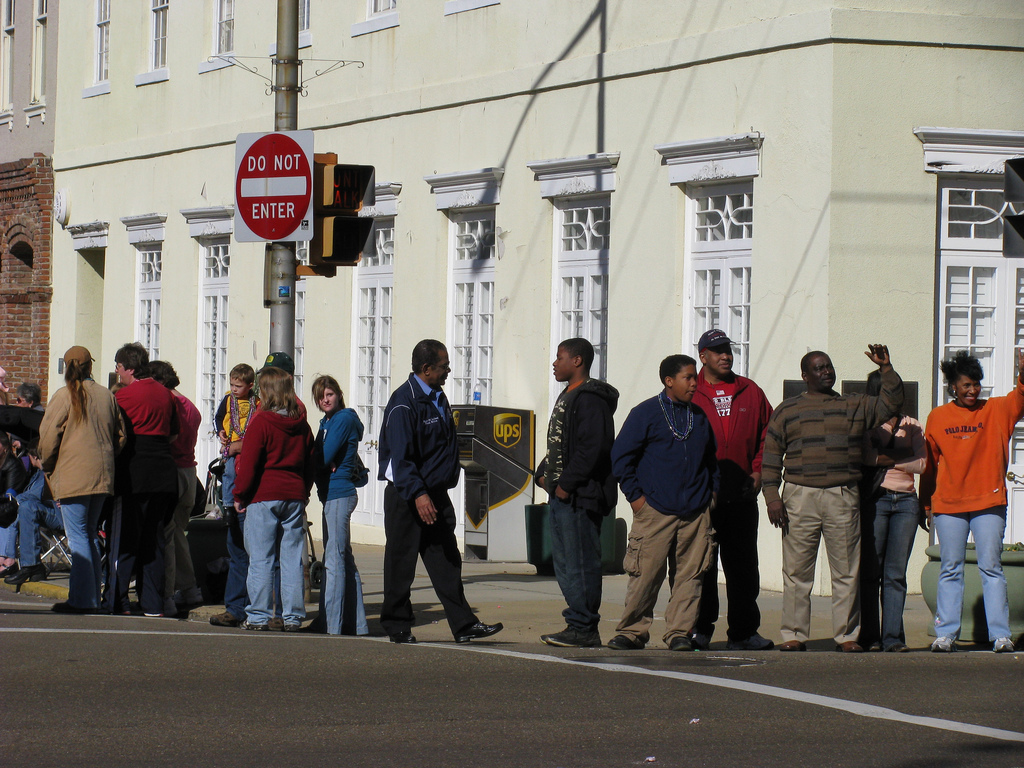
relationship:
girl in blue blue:
[308, 375, 372, 639] [611, 389, 721, 515]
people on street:
[14, 338, 1010, 655] [3, 575, 1023, 761]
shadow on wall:
[470, 6, 608, 390] [1, 2, 1021, 596]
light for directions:
[315, 152, 374, 275] [336, 171, 374, 209]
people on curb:
[14, 338, 1010, 655] [5, 562, 1020, 652]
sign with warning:
[241, 131, 315, 243] [249, 157, 304, 223]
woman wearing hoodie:
[237, 364, 318, 636] [232, 406, 315, 506]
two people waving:
[756, 343, 1021, 653] [867, 341, 1020, 430]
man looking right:
[377, 339, 504, 642] [449, 343, 1022, 623]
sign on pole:
[241, 131, 315, 243] [270, 6, 295, 398]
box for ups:
[451, 403, 536, 564] [489, 409, 531, 449]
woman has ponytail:
[31, 347, 129, 616] [69, 362, 88, 421]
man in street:
[377, 339, 504, 642] [3, 575, 1022, 761]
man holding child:
[264, 354, 302, 386] [209, 362, 260, 511]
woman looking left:
[308, 375, 372, 639] [14, 377, 309, 629]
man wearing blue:
[618, 354, 711, 657] [616, 390, 720, 513]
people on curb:
[156, 335, 370, 636] [1, 570, 1017, 651]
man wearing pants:
[763, 343, 903, 649] [782, 475, 865, 647]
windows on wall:
[124, 129, 1019, 553] [1, 2, 1021, 596]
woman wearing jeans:
[31, 347, 129, 616] [58, 492, 103, 609]